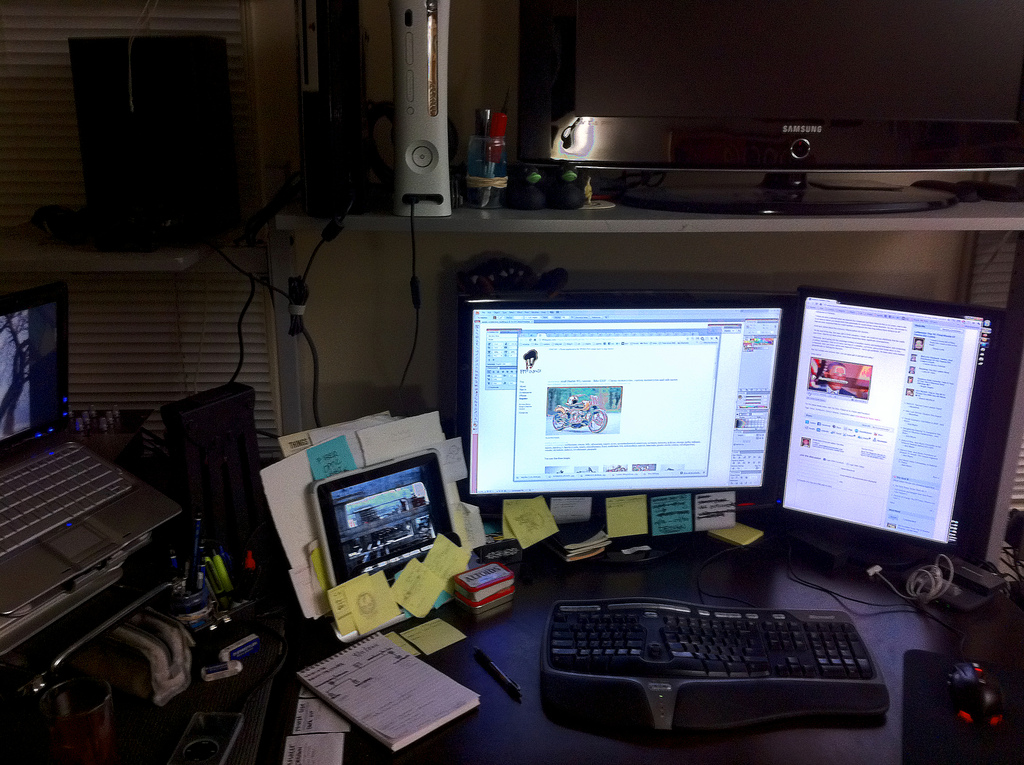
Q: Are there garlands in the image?
A: No, there are no garlands.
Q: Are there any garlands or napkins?
A: No, there are no garlands or napkins.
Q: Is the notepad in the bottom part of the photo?
A: Yes, the notepad is in the bottom of the image.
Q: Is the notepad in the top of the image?
A: No, the notepad is in the bottom of the image.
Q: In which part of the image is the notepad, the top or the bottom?
A: The notepad is in the bottom of the image.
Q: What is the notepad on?
A: The notepad is on the table.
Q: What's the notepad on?
A: The notepad is on the table.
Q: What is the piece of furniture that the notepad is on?
A: The piece of furniture is a table.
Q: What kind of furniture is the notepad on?
A: The notepad is on the table.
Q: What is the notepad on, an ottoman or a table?
A: The notepad is on a table.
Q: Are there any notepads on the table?
A: Yes, there is a notepad on the table.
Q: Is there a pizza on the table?
A: No, there is a notepad on the table.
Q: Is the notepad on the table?
A: Yes, the notepad is on the table.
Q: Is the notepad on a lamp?
A: No, the notepad is on the table.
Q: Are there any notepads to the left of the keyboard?
A: Yes, there is a notepad to the left of the keyboard.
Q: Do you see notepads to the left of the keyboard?
A: Yes, there is a notepad to the left of the keyboard.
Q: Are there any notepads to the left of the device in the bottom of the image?
A: Yes, there is a notepad to the left of the keyboard.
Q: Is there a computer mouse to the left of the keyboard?
A: No, there is a notepad to the left of the keyboard.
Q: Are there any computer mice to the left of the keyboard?
A: No, there is a notepad to the left of the keyboard.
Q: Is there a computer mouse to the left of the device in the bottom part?
A: No, there is a notepad to the left of the keyboard.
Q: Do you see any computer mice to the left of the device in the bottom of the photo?
A: No, there is a notepad to the left of the keyboard.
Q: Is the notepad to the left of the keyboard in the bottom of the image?
A: Yes, the notepad is to the left of the keyboard.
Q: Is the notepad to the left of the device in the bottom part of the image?
A: Yes, the notepad is to the left of the keyboard.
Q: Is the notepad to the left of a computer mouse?
A: No, the notepad is to the left of the keyboard.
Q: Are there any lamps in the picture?
A: No, there are no lamps.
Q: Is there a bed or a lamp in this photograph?
A: No, there are no lamps or beds.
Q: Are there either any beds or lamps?
A: No, there are no lamps or beds.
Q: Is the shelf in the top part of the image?
A: Yes, the shelf is in the top of the image.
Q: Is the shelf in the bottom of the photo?
A: No, the shelf is in the top of the image.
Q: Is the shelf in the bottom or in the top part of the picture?
A: The shelf is in the top of the image.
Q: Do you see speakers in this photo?
A: Yes, there is a speaker.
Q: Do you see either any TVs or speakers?
A: Yes, there is a speaker.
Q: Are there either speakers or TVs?
A: Yes, there is a speaker.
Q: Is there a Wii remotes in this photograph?
A: No, there are no Wii controllers.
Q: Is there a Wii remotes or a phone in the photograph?
A: No, there are no Wii controllers or phones.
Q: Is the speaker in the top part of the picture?
A: Yes, the speaker is in the top of the image.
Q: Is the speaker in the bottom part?
A: No, the speaker is in the top of the image.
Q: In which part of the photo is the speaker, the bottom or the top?
A: The speaker is in the top of the image.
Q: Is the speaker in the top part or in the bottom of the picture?
A: The speaker is in the top of the image.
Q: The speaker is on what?
A: The speaker is on the shelf.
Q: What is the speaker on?
A: The speaker is on the shelf.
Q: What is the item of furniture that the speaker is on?
A: The piece of furniture is a shelf.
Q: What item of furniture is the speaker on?
A: The speaker is on the shelf.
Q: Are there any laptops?
A: Yes, there is a laptop.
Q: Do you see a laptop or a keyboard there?
A: Yes, there is a laptop.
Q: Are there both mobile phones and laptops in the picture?
A: No, there is a laptop but no cell phones.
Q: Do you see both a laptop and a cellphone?
A: No, there is a laptop but no cell phones.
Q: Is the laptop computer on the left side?
A: Yes, the laptop computer is on the left of the image.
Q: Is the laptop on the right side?
A: No, the laptop is on the left of the image.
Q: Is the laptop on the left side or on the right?
A: The laptop is on the left of the image.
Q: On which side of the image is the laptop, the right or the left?
A: The laptop is on the left of the image.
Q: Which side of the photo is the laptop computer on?
A: The laptop computer is on the left of the image.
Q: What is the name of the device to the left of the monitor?
A: The device is a laptop.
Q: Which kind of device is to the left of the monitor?
A: The device is a laptop.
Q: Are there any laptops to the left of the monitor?
A: Yes, there is a laptop to the left of the monitor.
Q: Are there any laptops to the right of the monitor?
A: No, the laptop is to the left of the monitor.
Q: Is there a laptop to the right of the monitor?
A: No, the laptop is to the left of the monitor.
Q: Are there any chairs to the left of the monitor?
A: No, there is a laptop to the left of the monitor.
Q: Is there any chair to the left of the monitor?
A: No, there is a laptop to the left of the monitor.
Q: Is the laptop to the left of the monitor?
A: Yes, the laptop is to the left of the monitor.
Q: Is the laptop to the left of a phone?
A: No, the laptop is to the left of the monitor.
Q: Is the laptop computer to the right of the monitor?
A: No, the laptop computer is to the left of the monitor.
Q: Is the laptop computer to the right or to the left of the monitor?
A: The laptop computer is to the left of the monitor.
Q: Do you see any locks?
A: No, there are no locks.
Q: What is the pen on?
A: The pen is on the table.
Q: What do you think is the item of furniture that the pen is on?
A: The piece of furniture is a table.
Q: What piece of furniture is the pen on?
A: The pen is on the table.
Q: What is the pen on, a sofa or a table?
A: The pen is on a table.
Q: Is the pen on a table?
A: Yes, the pen is on a table.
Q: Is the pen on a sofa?
A: No, the pen is on a table.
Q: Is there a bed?
A: No, there are no beds.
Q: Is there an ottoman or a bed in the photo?
A: No, there are no beds or ottomen.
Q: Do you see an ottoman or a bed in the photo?
A: No, there are no beds or ottomen.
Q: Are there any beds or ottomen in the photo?
A: No, there are no beds or ottomen.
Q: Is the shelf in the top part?
A: Yes, the shelf is in the top of the image.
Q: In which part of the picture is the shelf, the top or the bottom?
A: The shelf is in the top of the image.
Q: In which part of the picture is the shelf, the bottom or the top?
A: The shelf is in the top of the image.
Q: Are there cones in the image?
A: No, there are no cones.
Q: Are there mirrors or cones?
A: No, there are no cones or mirrors.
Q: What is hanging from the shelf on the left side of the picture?
A: The cords are hanging from the shelf.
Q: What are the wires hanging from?
A: The wires are hanging from the shelf.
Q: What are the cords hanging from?
A: The wires are hanging from the shelf.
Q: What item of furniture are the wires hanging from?
A: The wires are hanging from the shelf.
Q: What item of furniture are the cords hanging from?
A: The wires are hanging from the shelf.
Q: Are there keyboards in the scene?
A: Yes, there is a keyboard.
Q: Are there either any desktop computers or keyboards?
A: Yes, there is a keyboard.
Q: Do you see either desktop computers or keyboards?
A: Yes, there is a keyboard.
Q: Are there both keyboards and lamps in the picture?
A: No, there is a keyboard but no lamps.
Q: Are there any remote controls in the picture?
A: No, there are no remote controls.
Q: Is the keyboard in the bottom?
A: Yes, the keyboard is in the bottom of the image.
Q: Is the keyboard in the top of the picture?
A: No, the keyboard is in the bottom of the image.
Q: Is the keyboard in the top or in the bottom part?
A: The keyboard is in the bottom of the image.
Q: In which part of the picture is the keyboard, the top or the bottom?
A: The keyboard is in the bottom of the image.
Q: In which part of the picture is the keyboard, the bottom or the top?
A: The keyboard is in the bottom of the image.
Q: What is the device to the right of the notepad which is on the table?
A: The device is a keyboard.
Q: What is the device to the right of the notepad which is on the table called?
A: The device is a keyboard.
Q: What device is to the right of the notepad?
A: The device is a keyboard.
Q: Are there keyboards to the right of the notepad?
A: Yes, there is a keyboard to the right of the notepad.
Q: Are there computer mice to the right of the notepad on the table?
A: No, there is a keyboard to the right of the notepad.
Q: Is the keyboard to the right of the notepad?
A: Yes, the keyboard is to the right of the notepad.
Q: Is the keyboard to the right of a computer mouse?
A: No, the keyboard is to the right of the notepad.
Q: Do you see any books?
A: No, there are no books.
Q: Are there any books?
A: No, there are no books.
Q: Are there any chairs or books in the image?
A: No, there are no books or chairs.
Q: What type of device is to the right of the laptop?
A: The device is a monitor.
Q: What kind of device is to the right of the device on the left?
A: The device is a monitor.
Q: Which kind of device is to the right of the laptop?
A: The device is a monitor.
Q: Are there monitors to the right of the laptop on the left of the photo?
A: Yes, there is a monitor to the right of the laptop.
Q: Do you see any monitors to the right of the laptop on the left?
A: Yes, there is a monitor to the right of the laptop.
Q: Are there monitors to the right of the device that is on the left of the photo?
A: Yes, there is a monitor to the right of the laptop.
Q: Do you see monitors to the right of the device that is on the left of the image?
A: Yes, there is a monitor to the right of the laptop.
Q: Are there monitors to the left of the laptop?
A: No, the monitor is to the right of the laptop.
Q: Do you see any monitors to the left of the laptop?
A: No, the monitor is to the right of the laptop.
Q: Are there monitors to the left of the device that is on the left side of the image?
A: No, the monitor is to the right of the laptop.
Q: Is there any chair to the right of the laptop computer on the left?
A: No, there is a monitor to the right of the laptop.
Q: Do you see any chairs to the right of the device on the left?
A: No, there is a monitor to the right of the laptop.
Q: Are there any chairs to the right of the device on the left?
A: No, there is a monitor to the right of the laptop.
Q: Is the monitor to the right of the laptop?
A: Yes, the monitor is to the right of the laptop.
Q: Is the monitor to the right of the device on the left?
A: Yes, the monitor is to the right of the laptop.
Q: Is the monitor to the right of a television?
A: No, the monitor is to the right of the laptop.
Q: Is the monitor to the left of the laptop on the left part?
A: No, the monitor is to the right of the laptop.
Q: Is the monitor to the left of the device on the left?
A: No, the monitor is to the right of the laptop.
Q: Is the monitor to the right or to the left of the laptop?
A: The monitor is to the right of the laptop.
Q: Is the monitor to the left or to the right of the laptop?
A: The monitor is to the right of the laptop.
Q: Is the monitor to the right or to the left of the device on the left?
A: The monitor is to the right of the laptop.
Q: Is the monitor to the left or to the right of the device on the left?
A: The monitor is to the right of the laptop.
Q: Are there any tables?
A: Yes, there is a table.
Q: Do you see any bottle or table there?
A: Yes, there is a table.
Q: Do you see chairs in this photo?
A: No, there are no chairs.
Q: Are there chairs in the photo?
A: No, there are no chairs.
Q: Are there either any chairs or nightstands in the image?
A: No, there are no chairs or nightstands.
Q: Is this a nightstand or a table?
A: This is a table.